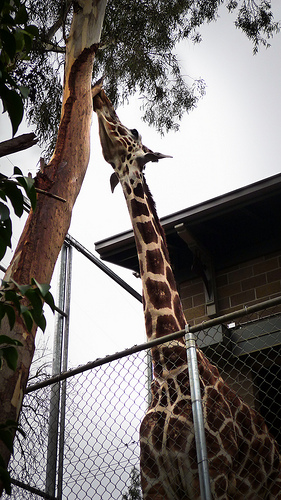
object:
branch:
[86, 79, 108, 98]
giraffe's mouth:
[92, 87, 116, 113]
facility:
[97, 166, 277, 473]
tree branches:
[5, 18, 67, 57]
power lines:
[71, 458, 132, 475]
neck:
[117, 173, 187, 322]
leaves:
[150, 25, 151, 29]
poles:
[62, 243, 73, 370]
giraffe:
[93, 89, 281, 500]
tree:
[0, 0, 279, 496]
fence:
[1, 296, 281, 497]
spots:
[220, 418, 238, 458]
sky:
[75, 288, 125, 341]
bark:
[50, 151, 74, 187]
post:
[185, 334, 211, 498]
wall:
[218, 245, 271, 289]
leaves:
[28, 274, 51, 304]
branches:
[2, 169, 69, 208]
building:
[94, 172, 280, 498]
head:
[89, 84, 174, 193]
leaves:
[0, 87, 23, 140]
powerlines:
[62, 439, 140, 460]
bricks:
[178, 283, 206, 300]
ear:
[109, 170, 120, 192]